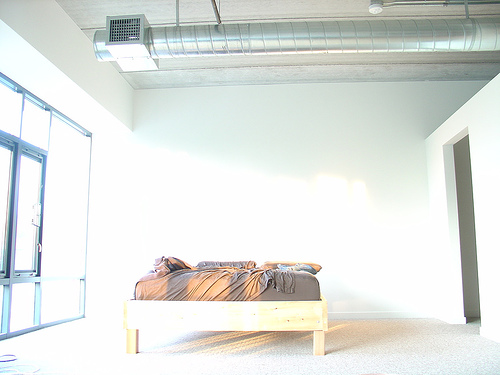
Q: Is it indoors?
A: Yes, it is indoors.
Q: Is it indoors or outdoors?
A: It is indoors.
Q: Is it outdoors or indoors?
A: It is indoors.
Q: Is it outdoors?
A: No, it is indoors.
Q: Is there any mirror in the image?
A: No, there are no mirrors.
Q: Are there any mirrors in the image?
A: No, there are no mirrors.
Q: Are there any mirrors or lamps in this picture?
A: No, there are no mirrors or lamps.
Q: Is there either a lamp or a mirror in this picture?
A: No, there are no mirrors or lamps.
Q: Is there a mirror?
A: No, there are no mirrors.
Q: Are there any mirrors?
A: No, there are no mirrors.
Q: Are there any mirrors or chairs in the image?
A: No, there are no mirrors or chairs.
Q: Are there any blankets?
A: Yes, there is a blanket.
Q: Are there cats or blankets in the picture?
A: Yes, there is a blanket.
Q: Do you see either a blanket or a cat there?
A: Yes, there is a blanket.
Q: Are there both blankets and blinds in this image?
A: No, there is a blanket but no blinds.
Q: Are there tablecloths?
A: No, there are no tablecloths.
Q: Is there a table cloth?
A: No, there are no tablecloths.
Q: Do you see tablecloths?
A: No, there are no tablecloths.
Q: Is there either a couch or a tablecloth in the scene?
A: No, there are no tablecloths or couches.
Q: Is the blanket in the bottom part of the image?
A: Yes, the blanket is in the bottom of the image.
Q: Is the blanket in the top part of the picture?
A: No, the blanket is in the bottom of the image.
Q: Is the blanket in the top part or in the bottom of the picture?
A: The blanket is in the bottom of the image.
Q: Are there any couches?
A: No, there are no couches.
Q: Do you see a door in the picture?
A: Yes, there is a door.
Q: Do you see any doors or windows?
A: Yes, there is a door.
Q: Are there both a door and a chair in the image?
A: No, there is a door but no chairs.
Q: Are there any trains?
A: No, there are no trains.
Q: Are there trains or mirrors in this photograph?
A: No, there are no trains or mirrors.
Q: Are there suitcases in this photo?
A: No, there are no suitcases.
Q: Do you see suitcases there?
A: No, there are no suitcases.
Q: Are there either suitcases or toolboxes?
A: No, there are no suitcases or toolboxes.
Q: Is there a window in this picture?
A: Yes, there is a window.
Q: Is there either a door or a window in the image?
A: Yes, there is a window.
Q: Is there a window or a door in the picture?
A: Yes, there is a window.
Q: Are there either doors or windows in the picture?
A: Yes, there is a window.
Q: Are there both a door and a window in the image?
A: Yes, there are both a window and a door.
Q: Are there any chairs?
A: No, there are no chairs.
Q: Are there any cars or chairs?
A: No, there are no chairs or cars.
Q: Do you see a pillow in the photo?
A: Yes, there are pillows.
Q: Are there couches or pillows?
A: Yes, there are pillows.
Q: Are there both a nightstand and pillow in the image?
A: No, there are pillows but no nightstands.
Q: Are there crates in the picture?
A: No, there are no crates.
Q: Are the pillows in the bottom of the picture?
A: Yes, the pillows are in the bottom of the image.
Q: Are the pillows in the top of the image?
A: No, the pillows are in the bottom of the image.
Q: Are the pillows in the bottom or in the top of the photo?
A: The pillows are in the bottom of the image.